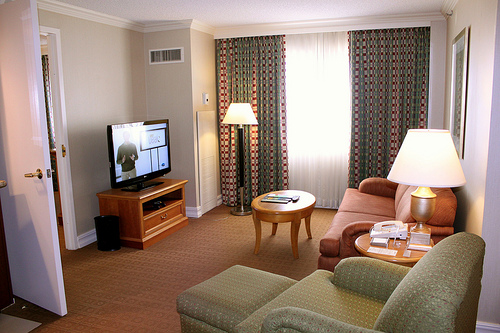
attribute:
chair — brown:
[231, 230, 486, 332]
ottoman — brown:
[177, 262, 299, 326]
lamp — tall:
[206, 76, 263, 240]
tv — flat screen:
[102, 117, 171, 192]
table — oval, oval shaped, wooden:
[249, 187, 317, 257]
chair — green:
[172, 230, 487, 330]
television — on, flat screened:
[107, 119, 174, 192]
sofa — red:
[318, 172, 458, 272]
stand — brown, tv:
[94, 155, 194, 257]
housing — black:
[104, 118, 173, 189]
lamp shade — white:
[386, 126, 466, 187]